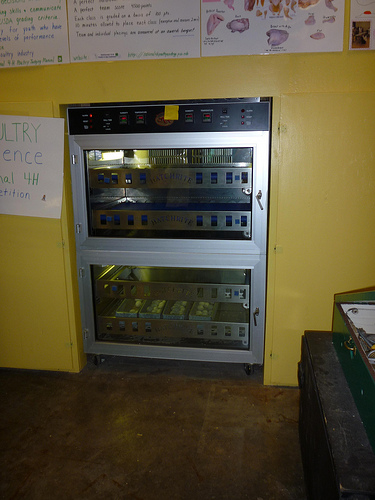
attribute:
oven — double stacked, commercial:
[63, 98, 272, 383]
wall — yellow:
[2, 1, 375, 384]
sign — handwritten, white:
[2, 112, 68, 219]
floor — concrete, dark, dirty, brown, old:
[2, 364, 308, 499]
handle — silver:
[255, 186, 266, 211]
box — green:
[331, 277, 373, 442]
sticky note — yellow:
[164, 103, 183, 121]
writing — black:
[70, 1, 200, 39]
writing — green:
[2, 2, 62, 26]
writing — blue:
[3, 25, 65, 70]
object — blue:
[209, 169, 221, 186]